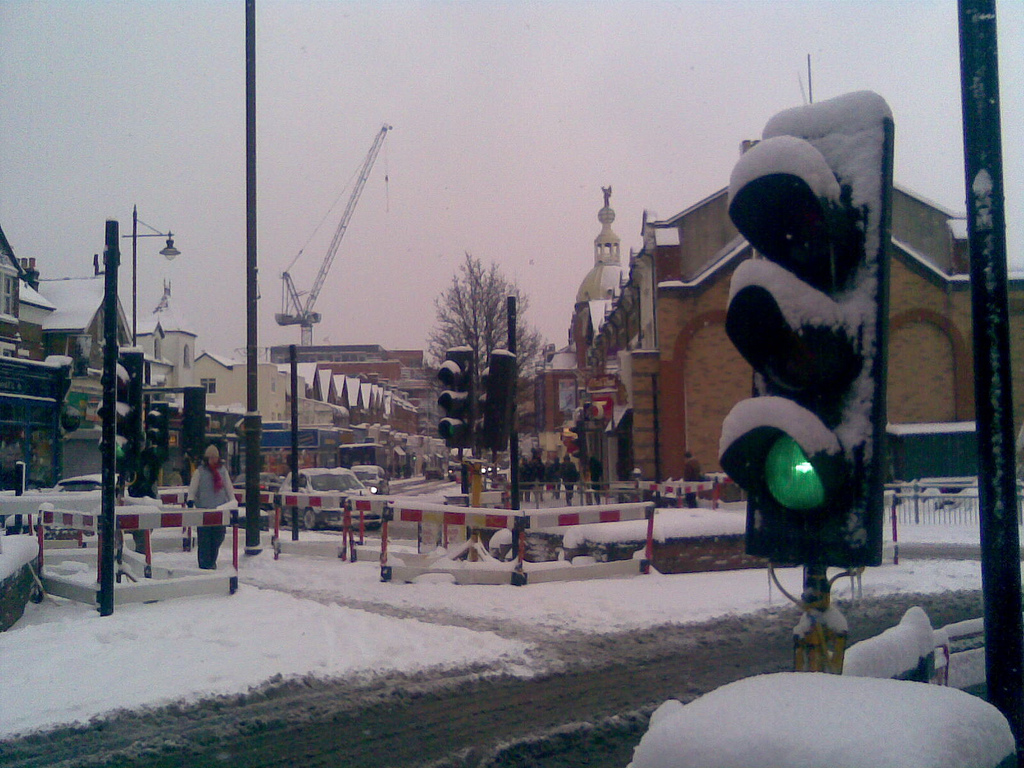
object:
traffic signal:
[695, 96, 908, 596]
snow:
[778, 113, 857, 157]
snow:
[733, 95, 898, 195]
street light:
[135, 193, 196, 328]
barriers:
[2, 482, 651, 606]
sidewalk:
[2, 492, 980, 737]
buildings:
[2, 164, 1002, 482]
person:
[180, 440, 248, 574]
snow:
[725, 89, 897, 215]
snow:
[720, 256, 871, 343]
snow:
[717, 380, 838, 460]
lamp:
[134, 219, 184, 265]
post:
[124, 208, 144, 355]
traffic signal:
[414, 337, 486, 445]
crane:
[266, 108, 413, 355]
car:
[280, 462, 389, 538]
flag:
[583, 386, 611, 429]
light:
[715, 89, 890, 558]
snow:
[707, 87, 891, 463]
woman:
[180, 441, 248, 573]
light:
[121, 209, 186, 344]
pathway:
[203, 572, 584, 657]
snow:
[2, 480, 983, 766]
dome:
[580, 258, 635, 303]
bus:
[336, 438, 397, 490]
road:
[269, 542, 497, 638]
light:
[695, 91, 905, 567]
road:
[5, 577, 980, 761]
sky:
[6, 0, 1021, 367]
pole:
[88, 214, 124, 599]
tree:
[435, 246, 539, 409]